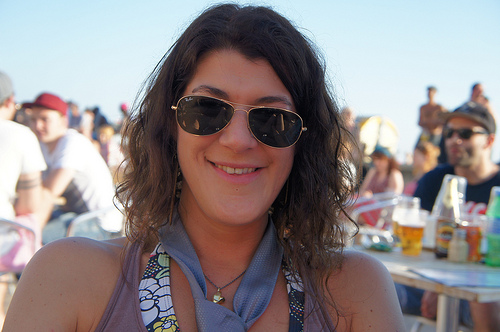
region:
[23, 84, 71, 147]
the head of a person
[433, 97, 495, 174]
the head of a person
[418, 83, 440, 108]
the head of a person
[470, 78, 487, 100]
the head of a person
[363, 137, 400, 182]
the head of a person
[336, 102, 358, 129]
the head of a person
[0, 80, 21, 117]
the head of a person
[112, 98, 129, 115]
the head of a person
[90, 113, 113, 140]
the head of a person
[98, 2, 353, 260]
the head of a person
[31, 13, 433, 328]
a girl at an outdoor beach bar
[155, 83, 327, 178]
the girls dark sunglasses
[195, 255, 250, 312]
the girl's gold necklace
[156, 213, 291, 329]
the men's neck tie around her neck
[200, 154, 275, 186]
the girl's toothy smile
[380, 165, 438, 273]
cups of beer on the table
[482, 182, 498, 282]
a green Sprite bottle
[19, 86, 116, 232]
a man wearing a white shirt and a red cap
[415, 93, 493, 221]
a man with a black cap and dark glasses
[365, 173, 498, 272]
drinks and condiments on the table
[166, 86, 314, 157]
the sunglasses the woman is wearing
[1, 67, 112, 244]
the man in the red hat talking to someone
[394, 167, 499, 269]
a table filled with assorted drinks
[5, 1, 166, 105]
a patch of blue sky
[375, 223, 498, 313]
a table holding assorted drinks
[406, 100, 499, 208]
a man standing by a bunch of drinks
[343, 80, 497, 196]
a group of people standing around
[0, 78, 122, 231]
more people standing around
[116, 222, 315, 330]
the clothes the woman is wearing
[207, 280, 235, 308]
the necklace around the woman's neck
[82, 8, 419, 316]
The woman is wearing gold aviator sunglasses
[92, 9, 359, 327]
The woman is wearing a purple shirt with a swimsuit underneath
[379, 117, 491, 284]
Multiple drinks are on top of the table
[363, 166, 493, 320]
The table top is white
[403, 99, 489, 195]
A man with a black hat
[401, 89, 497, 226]
A man with black sunglasses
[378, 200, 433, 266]
A cup full of yellow liquid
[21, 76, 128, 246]
A man with a red baseball cap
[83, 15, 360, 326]
The woman is wearing a necklace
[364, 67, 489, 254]
The people are sitting and standing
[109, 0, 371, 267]
Woman smiling at the camera.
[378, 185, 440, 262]
Alcoholic beer refreshments in plastic cups.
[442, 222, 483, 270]
Spicy mustard container for sandwiches.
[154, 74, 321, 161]
Sunglasses for eye protection.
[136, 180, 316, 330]
Men's necktie for wearing in dress up situations.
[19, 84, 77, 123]
Baseball cap for head protection.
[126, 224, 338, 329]
Bathing suit for swimming and suntanning.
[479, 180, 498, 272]
Clear soda in a plastic bottle.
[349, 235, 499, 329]
Outdoor table for placing items on.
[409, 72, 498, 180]
Shirtless people enjoying a sunny day.